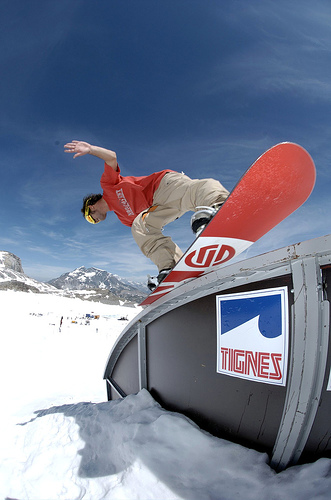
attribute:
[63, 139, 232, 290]
snowboarder — looking down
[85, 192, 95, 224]
goggles — yellow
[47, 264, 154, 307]
mountain — snowy, rocky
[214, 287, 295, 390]
sign — square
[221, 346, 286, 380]
word — red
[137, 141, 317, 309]
snowboard — red, white, big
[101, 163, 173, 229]
tshirt — red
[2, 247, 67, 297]
mountain — snowy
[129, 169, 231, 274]
pants — khaki, beige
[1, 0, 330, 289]
sky — blue, deep blue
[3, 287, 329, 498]
snow — ground, field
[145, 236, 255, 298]
design — white